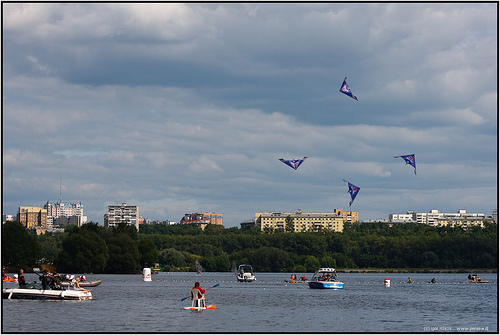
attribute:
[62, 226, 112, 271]
tree — green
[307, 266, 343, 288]
boat — blue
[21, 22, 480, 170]
skies — grey, cloudy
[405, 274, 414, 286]
person — swimming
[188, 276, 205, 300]
person — swimming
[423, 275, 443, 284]
person — swimming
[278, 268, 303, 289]
person — swimming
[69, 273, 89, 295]
person — swimming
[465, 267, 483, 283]
person — swimming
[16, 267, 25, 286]
person — swimming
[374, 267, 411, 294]
barrier — white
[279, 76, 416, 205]
kites — flying, Blue 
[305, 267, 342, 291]
boat — blue, white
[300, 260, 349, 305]
boat — white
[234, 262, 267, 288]
boat — white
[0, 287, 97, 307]
boat — white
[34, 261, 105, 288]
boat — white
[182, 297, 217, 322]
boat — white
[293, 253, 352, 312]
boat — blue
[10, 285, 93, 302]
watercraft — white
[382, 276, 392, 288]
buoy — orange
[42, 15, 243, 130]
sky — gray and white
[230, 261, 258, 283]
motorboat — white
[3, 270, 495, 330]
water — unchoppy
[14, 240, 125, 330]
raft — black, white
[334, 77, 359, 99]
kite — purple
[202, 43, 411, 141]
clouds — dark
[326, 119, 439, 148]
cloud — white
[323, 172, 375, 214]
kite — blue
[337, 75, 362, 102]
kite — blue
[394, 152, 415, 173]
kite — blue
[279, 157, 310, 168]
kite — blue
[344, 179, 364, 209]
kite — blue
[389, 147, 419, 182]
kite — four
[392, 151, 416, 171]
kites — Triangular, red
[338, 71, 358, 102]
kites — Triangular, red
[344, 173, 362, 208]
kites — Triangular, red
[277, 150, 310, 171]
kites — Triangular, red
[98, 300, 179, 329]
water — blue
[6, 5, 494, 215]
clouds — blue , gray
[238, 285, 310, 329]
water — green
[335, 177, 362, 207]
kite —  flying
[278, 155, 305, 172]
kite —  flying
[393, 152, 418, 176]
kite —  flying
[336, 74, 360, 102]
kite —  flying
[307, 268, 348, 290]
boat — blue and white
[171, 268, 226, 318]
person — floating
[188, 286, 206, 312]
lawn chair — floating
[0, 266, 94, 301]
boat — floating